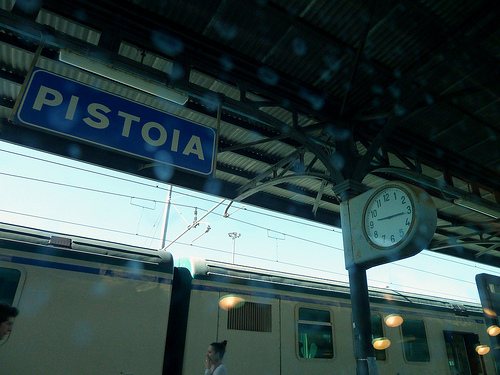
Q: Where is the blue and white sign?
A: Hanging from the ceiling.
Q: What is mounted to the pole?
A: A clock.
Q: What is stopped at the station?
A: A train.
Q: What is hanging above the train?
A: A blue and white sign.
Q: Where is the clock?
A: Mounted on a pole.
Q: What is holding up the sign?
A: Pole.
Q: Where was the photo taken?
A: Train station.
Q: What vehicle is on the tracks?
A: Train.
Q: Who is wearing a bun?
A: The woman.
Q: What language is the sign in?
A: Foreign language.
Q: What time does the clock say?
A: 9:15.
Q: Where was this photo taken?
A: At a train stop.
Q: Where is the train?
A: Behind the person.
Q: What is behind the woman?
A: A train.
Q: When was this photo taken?
A: During the daytime.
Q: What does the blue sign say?
A: Pistoia.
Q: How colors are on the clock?
A: Black and white.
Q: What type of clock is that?
A: An analog clock.